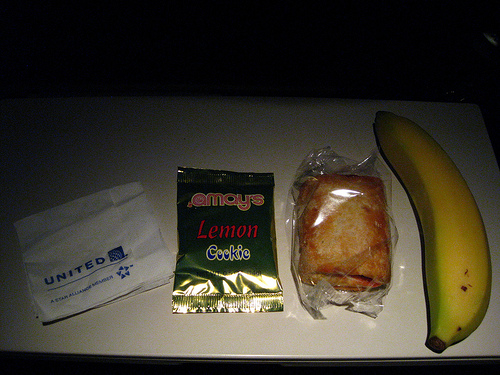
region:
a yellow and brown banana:
[428, 123, 478, 374]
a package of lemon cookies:
[172, 178, 281, 346]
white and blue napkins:
[11, 202, 161, 326]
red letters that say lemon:
[182, 220, 265, 242]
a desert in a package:
[260, 178, 390, 340]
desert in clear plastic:
[273, 167, 394, 337]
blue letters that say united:
[27, 252, 106, 290]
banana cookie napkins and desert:
[13, 180, 495, 313]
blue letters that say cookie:
[192, 241, 259, 267]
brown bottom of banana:
[385, 323, 475, 373]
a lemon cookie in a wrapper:
[164, 173, 298, 318]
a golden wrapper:
[167, 165, 288, 316]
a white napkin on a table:
[1, 194, 175, 310]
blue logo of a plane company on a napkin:
[37, 239, 157, 301]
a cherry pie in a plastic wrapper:
[283, 150, 398, 325]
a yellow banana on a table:
[386, 117, 496, 361]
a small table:
[21, 104, 498, 374]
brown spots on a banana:
[447, 253, 482, 333]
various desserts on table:
[177, 97, 498, 360]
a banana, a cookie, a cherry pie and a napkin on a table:
[18, 80, 498, 367]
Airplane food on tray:
[25, 148, 487, 339]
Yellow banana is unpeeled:
[378, 95, 491, 339]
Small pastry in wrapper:
[301, 136, 387, 302]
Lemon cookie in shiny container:
[178, 170, 278, 315]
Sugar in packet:
[30, 214, 158, 305]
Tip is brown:
[425, 327, 453, 363]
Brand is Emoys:
[185, 186, 265, 209]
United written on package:
[33, 253, 113, 289]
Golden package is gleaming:
[173, 267, 283, 308]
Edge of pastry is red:
[308, 263, 380, 296]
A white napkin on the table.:
[45, 199, 177, 310]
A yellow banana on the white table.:
[373, 115, 491, 358]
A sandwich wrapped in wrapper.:
[268, 141, 407, 304]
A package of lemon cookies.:
[172, 145, 285, 306]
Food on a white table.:
[18, 136, 498, 321]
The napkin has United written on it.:
[36, 224, 157, 297]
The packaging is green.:
[178, 159, 281, 304]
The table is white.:
[45, 107, 446, 330]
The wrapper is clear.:
[270, 153, 396, 318]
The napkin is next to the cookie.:
[22, 158, 294, 335]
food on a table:
[18, 67, 497, 369]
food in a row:
[29, 56, 460, 371]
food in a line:
[1, 70, 472, 368]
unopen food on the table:
[44, 50, 485, 365]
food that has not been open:
[46, 75, 483, 355]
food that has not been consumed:
[35, 57, 461, 373]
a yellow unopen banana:
[325, 65, 485, 284]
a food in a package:
[272, 116, 435, 345]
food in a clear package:
[294, 141, 446, 373]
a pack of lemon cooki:
[171, 139, 308, 339]